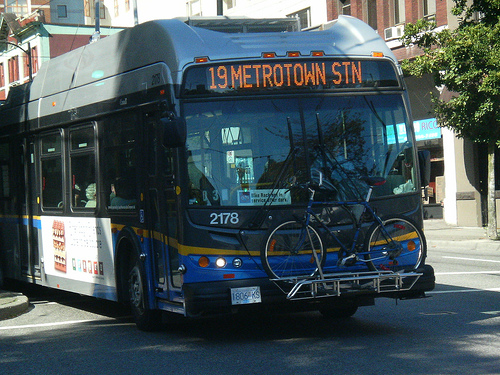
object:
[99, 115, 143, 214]
window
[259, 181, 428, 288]
bike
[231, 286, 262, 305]
numberplate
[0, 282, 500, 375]
shade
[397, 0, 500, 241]
tree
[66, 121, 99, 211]
window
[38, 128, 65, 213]
window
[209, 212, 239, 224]
number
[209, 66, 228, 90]
number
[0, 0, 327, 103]
buildings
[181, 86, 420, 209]
window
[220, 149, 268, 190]
part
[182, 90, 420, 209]
front screen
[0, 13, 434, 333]
bus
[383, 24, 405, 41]
ac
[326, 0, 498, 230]
building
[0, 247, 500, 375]
floor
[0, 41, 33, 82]
street light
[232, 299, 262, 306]
edge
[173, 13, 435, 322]
bus front